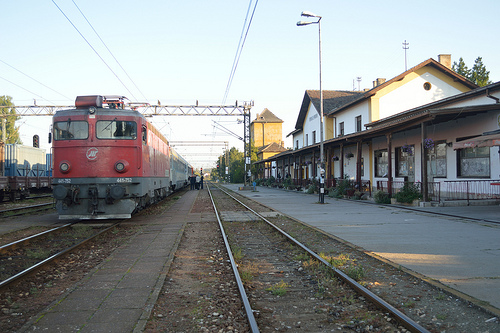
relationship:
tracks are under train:
[0, 220, 123, 290] [51, 96, 197, 223]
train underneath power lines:
[51, 96, 197, 223] [54, 0, 146, 99]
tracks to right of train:
[203, 191, 432, 331] [51, 96, 197, 223]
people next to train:
[188, 174, 204, 190] [51, 96, 197, 223]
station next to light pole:
[250, 53, 497, 203] [293, 9, 328, 206]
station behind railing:
[250, 53, 497, 203] [376, 180, 442, 204]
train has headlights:
[51, 96, 197, 223] [57, 160, 129, 175]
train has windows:
[51, 96, 197, 223] [55, 119, 138, 142]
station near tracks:
[250, 53, 497, 203] [203, 191, 432, 331]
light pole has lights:
[293, 9, 328, 206] [295, 11, 321, 28]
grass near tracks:
[267, 282, 290, 296] [203, 191, 432, 331]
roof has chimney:
[330, 57, 474, 111] [436, 52, 453, 68]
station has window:
[250, 53, 497, 203] [393, 142, 418, 178]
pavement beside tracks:
[227, 179, 500, 313] [203, 191, 432, 331]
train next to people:
[51, 96, 197, 223] [188, 174, 204, 190]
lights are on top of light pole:
[295, 11, 321, 28] [293, 9, 328, 206]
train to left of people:
[51, 96, 197, 223] [188, 174, 204, 190]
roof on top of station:
[330, 57, 474, 111] [250, 53, 497, 203]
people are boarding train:
[188, 174, 204, 190] [51, 96, 197, 223]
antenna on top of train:
[101, 97, 125, 109] [51, 96, 197, 223]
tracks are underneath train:
[0, 220, 123, 290] [51, 96, 197, 223]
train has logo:
[51, 96, 197, 223] [85, 143, 99, 161]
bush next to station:
[394, 180, 421, 203] [250, 53, 497, 203]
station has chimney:
[250, 53, 497, 203] [436, 52, 453, 68]